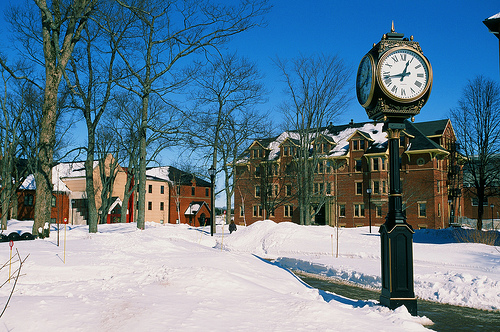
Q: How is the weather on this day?
A: It is clear.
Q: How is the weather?
A: It is clear.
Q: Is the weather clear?
A: Yes, it is clear.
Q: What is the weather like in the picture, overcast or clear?
A: It is clear.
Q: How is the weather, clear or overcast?
A: It is clear.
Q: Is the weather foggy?
A: No, it is clear.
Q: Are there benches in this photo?
A: No, there are no benches.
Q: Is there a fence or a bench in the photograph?
A: No, there are no benches or fences.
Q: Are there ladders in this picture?
A: No, there are no ladders.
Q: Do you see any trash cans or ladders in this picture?
A: No, there are no ladders or trash cans.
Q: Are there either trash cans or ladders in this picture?
A: No, there are no ladders or trash cans.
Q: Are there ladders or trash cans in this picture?
A: No, there are no ladders or trash cans.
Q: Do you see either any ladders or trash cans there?
A: No, there are no ladders or trash cans.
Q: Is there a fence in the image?
A: No, there are no fences.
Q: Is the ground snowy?
A: Yes, the ground is snowy.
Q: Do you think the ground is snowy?
A: Yes, the ground is snowy.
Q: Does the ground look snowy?
A: Yes, the ground is snowy.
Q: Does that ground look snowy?
A: Yes, the ground is snowy.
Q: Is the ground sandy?
A: No, the ground is snowy.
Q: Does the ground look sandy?
A: No, the ground is snowy.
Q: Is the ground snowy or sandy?
A: The ground is snowy.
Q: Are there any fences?
A: No, there are no fences.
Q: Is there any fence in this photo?
A: No, there are no fences.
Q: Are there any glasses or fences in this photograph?
A: No, there are no fences or glasses.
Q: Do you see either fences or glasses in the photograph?
A: No, there are no fences or glasses.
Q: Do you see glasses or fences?
A: No, there are no fences or glasses.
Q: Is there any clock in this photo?
A: Yes, there is a clock.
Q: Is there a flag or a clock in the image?
A: Yes, there is a clock.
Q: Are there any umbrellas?
A: No, there are no umbrellas.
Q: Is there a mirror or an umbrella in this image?
A: No, there are no umbrellas or mirrors.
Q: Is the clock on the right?
A: Yes, the clock is on the right of the image.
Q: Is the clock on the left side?
A: No, the clock is on the right of the image.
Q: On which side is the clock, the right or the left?
A: The clock is on the right of the image.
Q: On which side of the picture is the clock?
A: The clock is on the right of the image.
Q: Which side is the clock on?
A: The clock is on the right of the image.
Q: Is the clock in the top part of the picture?
A: Yes, the clock is in the top of the image.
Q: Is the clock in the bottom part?
A: No, the clock is in the top of the image.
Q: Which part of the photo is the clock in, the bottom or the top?
A: The clock is in the top of the image.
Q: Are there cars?
A: No, there are no cars.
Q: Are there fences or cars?
A: No, there are no cars or fences.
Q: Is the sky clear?
A: Yes, the sky is clear.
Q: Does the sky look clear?
A: Yes, the sky is clear.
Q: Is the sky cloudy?
A: No, the sky is clear.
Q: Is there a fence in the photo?
A: No, there are no fences.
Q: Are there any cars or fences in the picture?
A: No, there are no fences or cars.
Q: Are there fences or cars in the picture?
A: No, there are no fences or cars.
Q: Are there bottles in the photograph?
A: No, there are no bottles.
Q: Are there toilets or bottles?
A: No, there are no bottles or toilets.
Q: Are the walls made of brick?
A: Yes, the walls are made of brick.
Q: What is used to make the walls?
A: The walls are made of brick.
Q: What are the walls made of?
A: The walls are made of brick.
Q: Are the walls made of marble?
A: No, the walls are made of brick.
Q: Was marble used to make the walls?
A: No, the walls are made of brick.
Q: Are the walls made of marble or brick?
A: The walls are made of brick.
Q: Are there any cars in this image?
A: No, there are no cars.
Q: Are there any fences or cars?
A: No, there are no cars or fences.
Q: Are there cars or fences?
A: No, there are no cars or fences.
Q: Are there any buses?
A: No, there are no buses.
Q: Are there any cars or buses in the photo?
A: No, there are no buses or cars.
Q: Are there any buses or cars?
A: No, there are no buses or cars.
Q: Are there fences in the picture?
A: No, there are no fences.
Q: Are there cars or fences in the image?
A: No, there are no fences or cars.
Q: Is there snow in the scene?
A: Yes, there is snow.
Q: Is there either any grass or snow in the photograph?
A: Yes, there is snow.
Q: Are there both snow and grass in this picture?
A: No, there is snow but no grass.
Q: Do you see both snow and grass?
A: No, there is snow but no grass.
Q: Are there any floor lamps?
A: No, there are no floor lamps.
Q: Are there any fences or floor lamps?
A: No, there are no floor lamps or fences.